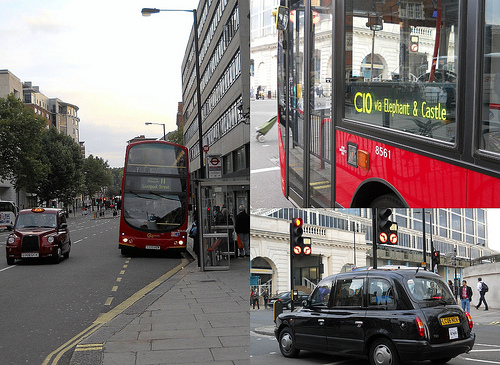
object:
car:
[274, 270, 473, 365]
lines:
[102, 257, 131, 306]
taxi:
[5, 206, 71, 265]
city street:
[0, 208, 196, 365]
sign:
[354, 92, 447, 121]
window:
[343, 0, 467, 152]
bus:
[271, 0, 500, 208]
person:
[458, 280, 473, 314]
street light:
[141, 8, 193, 18]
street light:
[144, 121, 164, 125]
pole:
[192, 9, 205, 267]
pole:
[163, 123, 166, 140]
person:
[261, 288, 270, 310]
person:
[252, 288, 261, 311]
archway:
[250, 256, 279, 307]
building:
[248, 208, 492, 306]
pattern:
[102, 258, 250, 364]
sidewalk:
[102, 257, 250, 364]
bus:
[116, 140, 194, 256]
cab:
[272, 269, 476, 365]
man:
[473, 277, 489, 311]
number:
[375, 146, 391, 160]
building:
[180, 0, 250, 216]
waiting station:
[189, 176, 250, 272]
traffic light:
[377, 207, 393, 231]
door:
[285, 0, 336, 208]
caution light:
[290, 217, 312, 257]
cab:
[5, 206, 71, 265]